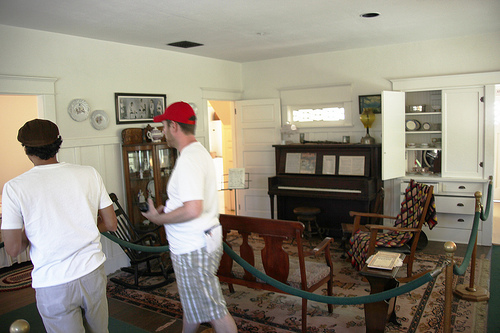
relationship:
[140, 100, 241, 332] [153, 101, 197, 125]
man has on a cap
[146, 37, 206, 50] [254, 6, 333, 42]
vent in ceiling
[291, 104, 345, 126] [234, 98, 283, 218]
window behind door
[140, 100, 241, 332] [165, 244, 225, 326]
man wearing shorts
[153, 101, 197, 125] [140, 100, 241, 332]
cap on man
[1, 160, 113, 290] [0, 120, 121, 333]
t shirt on man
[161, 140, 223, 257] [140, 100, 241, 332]
t shirt on man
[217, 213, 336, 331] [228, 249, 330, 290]
bench has cushion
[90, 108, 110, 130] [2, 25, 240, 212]
plate on wall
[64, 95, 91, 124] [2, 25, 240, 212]
plate on wall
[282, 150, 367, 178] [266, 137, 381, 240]
mic sheets on piano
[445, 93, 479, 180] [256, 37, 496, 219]
cabinet on wall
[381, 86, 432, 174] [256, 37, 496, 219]
cabinet on wall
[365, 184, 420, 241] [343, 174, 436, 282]
blanket on rocker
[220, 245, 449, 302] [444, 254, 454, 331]
rope on stick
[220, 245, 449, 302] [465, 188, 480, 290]
rope on stick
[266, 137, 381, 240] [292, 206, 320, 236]
piano with stool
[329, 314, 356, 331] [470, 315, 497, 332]
rug on floor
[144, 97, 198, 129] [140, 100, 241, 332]
cap on man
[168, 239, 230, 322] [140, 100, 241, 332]
shorts on man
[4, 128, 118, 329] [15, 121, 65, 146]
man wearing brown hat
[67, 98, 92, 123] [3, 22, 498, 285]
plate on wall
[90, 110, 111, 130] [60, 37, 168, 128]
plate on wall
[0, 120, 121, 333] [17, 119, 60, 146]
man wearing brown hat